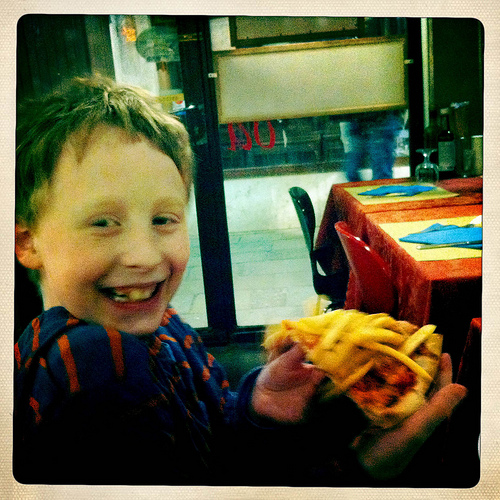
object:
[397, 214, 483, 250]
napkin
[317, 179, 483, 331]
table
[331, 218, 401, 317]
chair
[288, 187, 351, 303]
chair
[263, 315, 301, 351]
frey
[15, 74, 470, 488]
boy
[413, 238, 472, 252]
knife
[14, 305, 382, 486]
hoodie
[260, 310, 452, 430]
fry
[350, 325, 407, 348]
french fry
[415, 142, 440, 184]
glass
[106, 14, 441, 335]
window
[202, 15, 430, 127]
board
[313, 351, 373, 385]
french fry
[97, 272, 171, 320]
smiling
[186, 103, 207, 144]
handle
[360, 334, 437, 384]
french fry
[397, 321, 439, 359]
french fry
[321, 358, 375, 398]
french fry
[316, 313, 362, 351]
french fry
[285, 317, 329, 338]
french fry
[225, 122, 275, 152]
writing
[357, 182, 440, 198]
napkin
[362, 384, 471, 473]
finger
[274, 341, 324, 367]
finger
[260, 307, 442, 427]
pizza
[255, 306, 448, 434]
slice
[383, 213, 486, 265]
plate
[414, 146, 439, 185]
upside down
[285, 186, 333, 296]
backing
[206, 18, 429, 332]
outside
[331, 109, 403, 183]
people